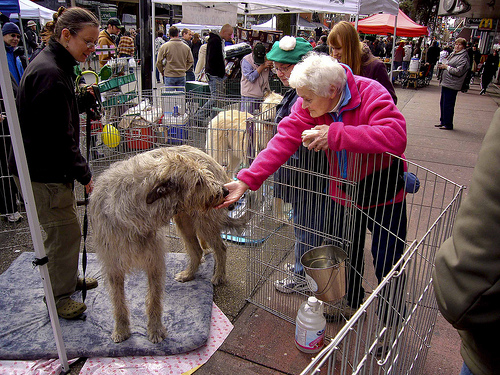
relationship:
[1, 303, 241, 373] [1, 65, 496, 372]
floor on floor